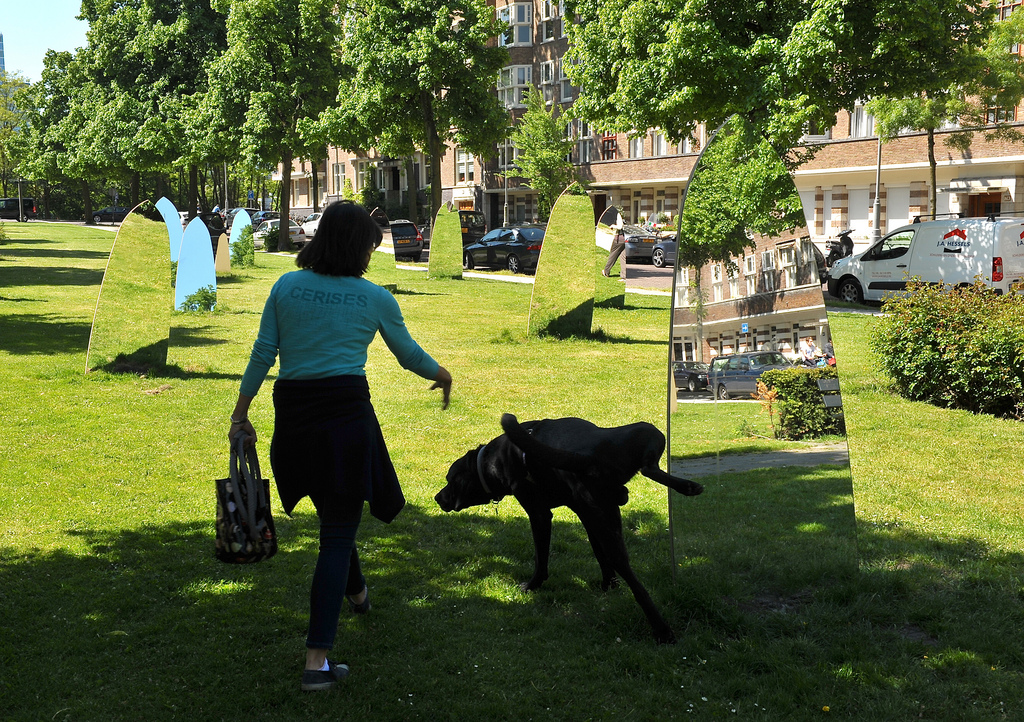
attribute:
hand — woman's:
[228, 415, 261, 454]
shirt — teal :
[238, 275, 441, 392]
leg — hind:
[607, 414, 707, 501]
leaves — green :
[6, 19, 975, 138]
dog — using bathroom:
[454, 365, 720, 514]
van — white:
[816, 215, 1022, 307]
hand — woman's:
[222, 405, 268, 457]